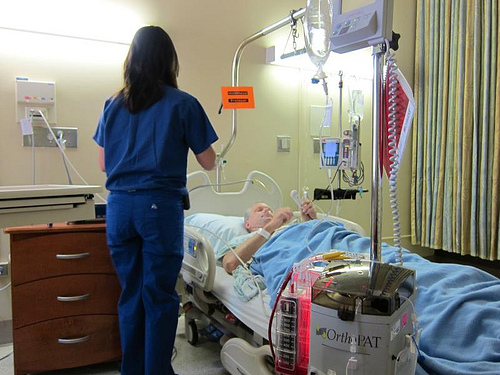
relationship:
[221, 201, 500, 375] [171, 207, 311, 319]
man laying in a hospital bed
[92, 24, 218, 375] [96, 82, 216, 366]
lady wearing scrub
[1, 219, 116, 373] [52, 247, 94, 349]
cabinet with handles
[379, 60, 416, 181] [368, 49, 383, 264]
folder hanging from a pole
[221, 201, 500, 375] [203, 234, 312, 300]
man lying in a bed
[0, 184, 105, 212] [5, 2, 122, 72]
tray attached to wall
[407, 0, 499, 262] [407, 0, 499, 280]
curtains over window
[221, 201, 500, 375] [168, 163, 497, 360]
man laying in a hospital bed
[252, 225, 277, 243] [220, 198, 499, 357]
bracelet on patient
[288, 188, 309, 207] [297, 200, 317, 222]
monitor in patients hand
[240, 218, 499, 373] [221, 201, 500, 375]
blanket on man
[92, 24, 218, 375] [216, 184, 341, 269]
lady checking on her patient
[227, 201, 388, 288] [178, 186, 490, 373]
man lying in a hospital bed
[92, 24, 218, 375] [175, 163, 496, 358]
lady standing beside bed